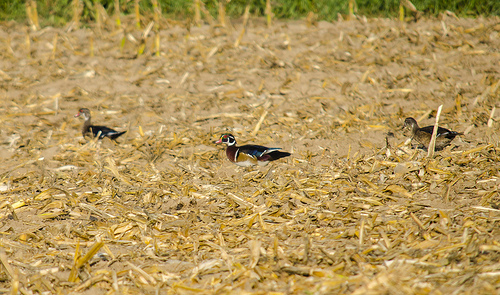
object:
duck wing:
[249, 147, 282, 159]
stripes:
[224, 137, 236, 147]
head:
[215, 133, 233, 145]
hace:
[402, 117, 415, 131]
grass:
[0, 0, 487, 42]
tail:
[109, 131, 127, 139]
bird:
[214, 133, 290, 171]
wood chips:
[351, 222, 367, 252]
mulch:
[10, 14, 497, 152]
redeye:
[224, 135, 227, 138]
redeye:
[81, 110, 83, 112]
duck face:
[403, 119, 414, 127]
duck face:
[220, 133, 232, 144]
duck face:
[78, 108, 85, 114]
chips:
[0, 12, 495, 294]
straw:
[354, 234, 483, 285]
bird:
[402, 118, 462, 151]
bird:
[76, 107, 127, 144]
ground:
[2, 1, 496, 292]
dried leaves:
[397, 236, 495, 288]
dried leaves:
[17, 210, 194, 289]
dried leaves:
[359, 32, 454, 87]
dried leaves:
[56, 44, 209, 109]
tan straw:
[425, 104, 442, 160]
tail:
[274, 151, 291, 158]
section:
[254, 149, 261, 156]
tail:
[449, 131, 465, 141]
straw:
[124, 163, 257, 252]